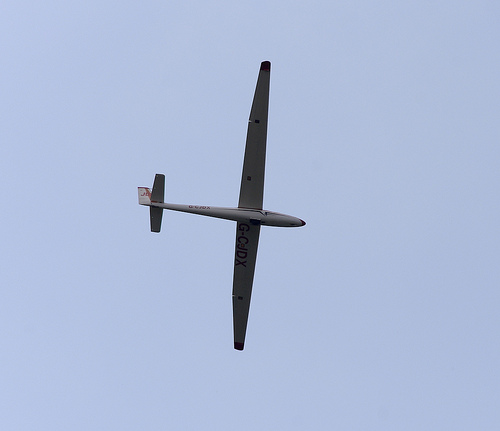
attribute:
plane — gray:
[134, 57, 313, 364]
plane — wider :
[127, 54, 324, 368]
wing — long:
[239, 60, 272, 209]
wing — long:
[229, 222, 258, 349]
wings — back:
[131, 155, 202, 257]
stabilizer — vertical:
[136, 184, 150, 207]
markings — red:
[138, 185, 151, 198]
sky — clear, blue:
[1, 3, 499, 428]